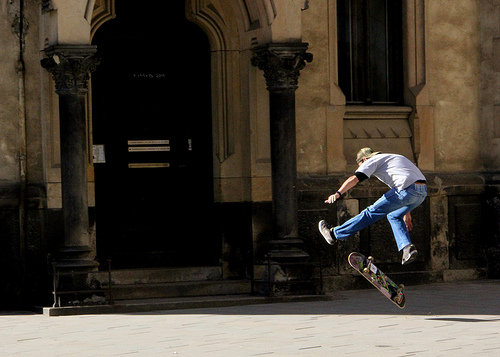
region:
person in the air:
[309, 143, 426, 268]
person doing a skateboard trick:
[316, 142, 431, 266]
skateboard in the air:
[342, 248, 412, 315]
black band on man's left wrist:
[332, 184, 344, 200]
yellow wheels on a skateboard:
[361, 250, 408, 304]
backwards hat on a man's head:
[355, 143, 382, 161]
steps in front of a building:
[86, 246, 261, 301]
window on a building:
[326, 1, 423, 121]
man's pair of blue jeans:
[330, 178, 430, 250]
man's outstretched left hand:
[320, 157, 376, 211]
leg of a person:
[307, 189, 401, 249]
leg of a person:
[385, 195, 428, 269]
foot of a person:
[312, 210, 339, 248]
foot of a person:
[398, 242, 423, 266]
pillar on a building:
[242, 21, 334, 302]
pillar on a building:
[47, 39, 107, 322]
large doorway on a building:
[77, 3, 252, 276]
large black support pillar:
[250, 28, 325, 293]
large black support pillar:
[31, 35, 113, 314]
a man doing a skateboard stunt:
[249, 112, 439, 313]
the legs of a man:
[318, 183, 430, 266]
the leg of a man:
[384, 208, 424, 270]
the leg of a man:
[301, 205, 384, 245]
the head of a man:
[346, 140, 384, 167]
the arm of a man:
[305, 165, 362, 215]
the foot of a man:
[314, 215, 338, 256]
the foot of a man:
[397, 241, 422, 266]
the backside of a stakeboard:
[345, 250, 412, 320]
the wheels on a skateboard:
[362, 253, 374, 277]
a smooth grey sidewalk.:
[176, 314, 321, 344]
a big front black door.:
[91, 2, 225, 264]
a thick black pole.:
[248, 36, 320, 292]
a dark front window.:
[331, 1, 416, 105]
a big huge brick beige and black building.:
[0, 0, 499, 147]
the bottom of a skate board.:
[347, 248, 407, 308]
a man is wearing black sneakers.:
[313, 217, 339, 246]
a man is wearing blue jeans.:
[396, 186, 422, 204]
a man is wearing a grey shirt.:
[391, 157, 405, 187]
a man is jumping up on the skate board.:
[314, 130, 434, 323]